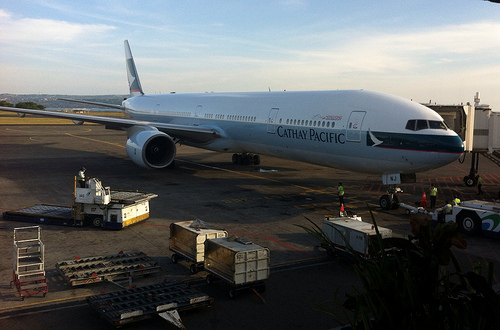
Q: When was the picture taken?
A: Daytime.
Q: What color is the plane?
A: White and blue.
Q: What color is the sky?
A: Blue.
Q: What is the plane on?
A: The asphalt.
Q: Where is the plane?
A: On the asphalt.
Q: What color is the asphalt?
A: Black.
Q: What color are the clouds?
A: White.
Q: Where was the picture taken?
A: At the airport.